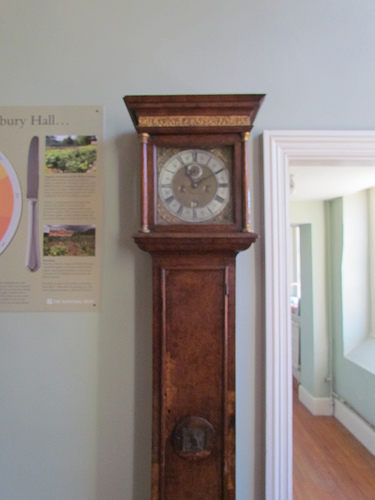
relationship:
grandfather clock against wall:
[117, 93, 264, 499] [11, 92, 262, 499]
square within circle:
[188, 159, 203, 179] [176, 161, 216, 209]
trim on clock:
[141, 115, 254, 131] [117, 93, 264, 499]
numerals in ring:
[161, 155, 229, 223] [159, 156, 227, 218]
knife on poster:
[29, 139, 45, 274] [4, 103, 118, 288]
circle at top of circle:
[189, 166, 207, 182] [176, 161, 216, 209]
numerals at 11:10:
[161, 155, 229, 223] [178, 161, 220, 190]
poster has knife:
[4, 103, 118, 288] [29, 139, 45, 274]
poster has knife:
[0, 104, 102, 312] [29, 139, 45, 274]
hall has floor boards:
[294, 171, 363, 496] [292, 390, 367, 500]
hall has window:
[294, 171, 363, 496] [340, 200, 374, 379]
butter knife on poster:
[29, 139, 45, 274] [4, 103, 118, 288]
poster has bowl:
[4, 103, 118, 288] [0, 157, 23, 249]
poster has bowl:
[0, 104, 102, 312] [1, 158, 19, 247]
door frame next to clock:
[260, 127, 374, 498] [117, 93, 264, 499]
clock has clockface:
[117, 93, 264, 499] [156, 145, 234, 224]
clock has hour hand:
[117, 93, 264, 499] [197, 167, 208, 186]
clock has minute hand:
[117, 93, 264, 499] [179, 158, 192, 189]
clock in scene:
[117, 93, 264, 499] [1, 4, 372, 499]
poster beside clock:
[4, 103, 118, 288] [117, 93, 264, 499]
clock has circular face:
[117, 93, 264, 499] [154, 145, 232, 219]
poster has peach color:
[0, 104, 102, 312] [0, 176, 14, 233]